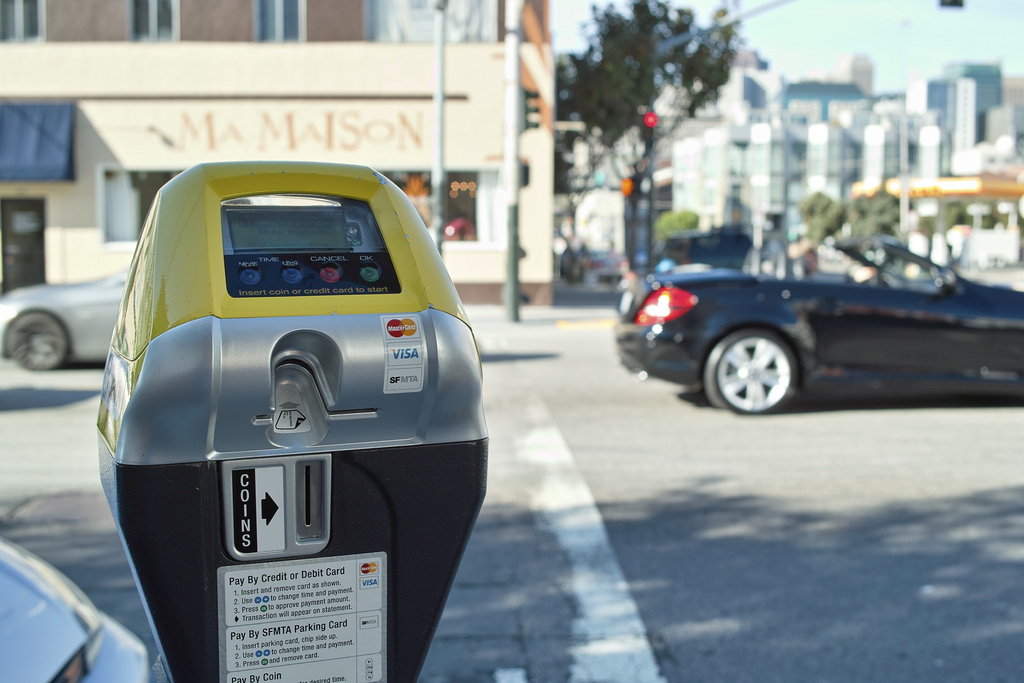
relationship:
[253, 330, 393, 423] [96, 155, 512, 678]
card slot on parking meter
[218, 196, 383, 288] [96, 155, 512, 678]
display on parking meter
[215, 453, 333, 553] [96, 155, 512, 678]
coin slot on parking meter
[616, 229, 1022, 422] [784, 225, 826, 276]
sportscar driven by white man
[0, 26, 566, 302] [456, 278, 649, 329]
boutique on street corner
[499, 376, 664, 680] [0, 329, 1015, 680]
white stripe on street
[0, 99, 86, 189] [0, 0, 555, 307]
awning on building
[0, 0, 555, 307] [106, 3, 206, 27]
building has window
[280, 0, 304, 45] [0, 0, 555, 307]
window has building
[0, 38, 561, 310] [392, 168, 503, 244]
building has window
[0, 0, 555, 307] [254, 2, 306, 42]
building has window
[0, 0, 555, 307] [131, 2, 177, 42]
building has window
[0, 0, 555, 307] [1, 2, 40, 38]
building has window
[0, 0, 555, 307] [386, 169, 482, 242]
building has window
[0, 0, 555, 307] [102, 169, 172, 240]
building has window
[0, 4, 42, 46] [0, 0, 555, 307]
window has building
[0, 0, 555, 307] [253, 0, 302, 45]
building has window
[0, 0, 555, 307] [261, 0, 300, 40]
building has window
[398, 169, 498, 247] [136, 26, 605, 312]
window in building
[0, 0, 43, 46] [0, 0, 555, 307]
window in building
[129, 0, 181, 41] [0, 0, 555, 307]
window in building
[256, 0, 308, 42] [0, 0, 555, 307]
window in building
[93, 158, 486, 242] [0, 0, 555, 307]
window in building